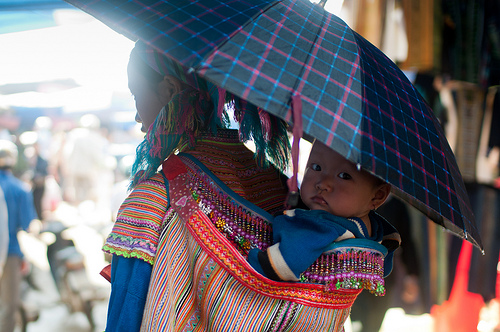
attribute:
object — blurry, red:
[423, 222, 494, 322]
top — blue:
[242, 209, 367, 280]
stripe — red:
[337, 115, 359, 132]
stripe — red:
[308, 68, 326, 80]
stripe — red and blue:
[325, 118, 339, 145]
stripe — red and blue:
[240, 71, 258, 101]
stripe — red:
[308, 44, 320, 65]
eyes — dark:
[311, 155, 358, 182]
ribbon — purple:
[282, 87, 304, 195]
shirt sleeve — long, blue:
[101, 247, 154, 330]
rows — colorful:
[199, 178, 206, 205]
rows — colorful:
[229, 199, 238, 238]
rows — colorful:
[253, 213, 259, 250]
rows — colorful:
[335, 250, 343, 289]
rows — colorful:
[356, 249, 363, 289]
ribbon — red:
[289, 93, 301, 188]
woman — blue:
[100, 26, 271, 330]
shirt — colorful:
[124, 142, 266, 220]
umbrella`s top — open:
[68, 3, 485, 255]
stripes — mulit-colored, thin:
[136, 196, 383, 329]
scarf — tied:
[130, 39, 288, 189]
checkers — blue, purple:
[279, 45, 365, 133]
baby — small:
[260, 125, 419, 305]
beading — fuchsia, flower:
[174, 178, 386, 290]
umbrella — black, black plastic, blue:
[69, 0, 484, 247]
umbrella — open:
[178, 3, 476, 144]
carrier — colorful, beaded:
[130, 145, 380, 325]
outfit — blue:
[251, 201, 373, 286]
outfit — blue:
[273, 133, 388, 267]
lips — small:
[304, 194, 330, 207]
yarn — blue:
[133, 39, 293, 187]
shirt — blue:
[2, 171, 38, 257]